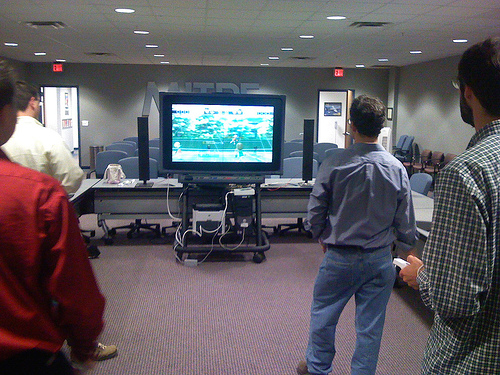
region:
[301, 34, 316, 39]
a small ceiling light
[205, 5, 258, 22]
a white ceiling tile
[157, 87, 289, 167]
a large black t.v.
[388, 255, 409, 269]
part of a white Wii controller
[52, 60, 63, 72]
a red and white emergency exit sign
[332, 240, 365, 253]
a man's black belt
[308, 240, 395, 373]
a man's blue jean pants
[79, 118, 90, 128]
a white light switch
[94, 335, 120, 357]
part of a man's shoe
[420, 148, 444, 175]
a brown chair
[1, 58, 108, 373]
A man in a red shirt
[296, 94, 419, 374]
A man wearing all blue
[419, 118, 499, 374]
A blue and white plaid shirt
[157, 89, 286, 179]
A flat screen tv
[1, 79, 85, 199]
A man in a white shirt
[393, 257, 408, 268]
A video game controller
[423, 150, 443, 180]
A brown chair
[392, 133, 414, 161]
A pair of blue chairs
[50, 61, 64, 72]
An exit sign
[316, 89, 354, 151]
An open door way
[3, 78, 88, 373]
man standing in room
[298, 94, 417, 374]
man standing in room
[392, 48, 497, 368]
man standing in room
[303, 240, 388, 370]
blue jeans of man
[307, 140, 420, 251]
blue shirt of man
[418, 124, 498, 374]
checkered shirt of man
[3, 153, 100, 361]
red shirt of man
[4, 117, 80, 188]
white shirt of man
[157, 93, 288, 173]
large tv in room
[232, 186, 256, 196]
Wii console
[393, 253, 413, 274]
Wii remote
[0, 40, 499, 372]
group of people playing video games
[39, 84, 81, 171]
Open door in the room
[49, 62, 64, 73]
Exit sign posted on top of the ceiling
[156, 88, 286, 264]
Cart with a television set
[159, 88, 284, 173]
Television posted on the cart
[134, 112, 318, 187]
Pair of speakers surrounding the computer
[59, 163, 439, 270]
Desk surrounding the computer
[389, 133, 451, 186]
Row of chairs next to the wall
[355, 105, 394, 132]
Man has dark hair.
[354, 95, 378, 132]
Man has short hair.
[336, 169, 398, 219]
Man wearing blue shirt.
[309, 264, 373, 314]
Man wearing blue jeans.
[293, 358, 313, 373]
Man wearing brown shoes.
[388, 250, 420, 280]
Person holding white controller.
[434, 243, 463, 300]
Person wearing plaid shirt.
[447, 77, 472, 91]
Glasses on person's face.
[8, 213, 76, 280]
Person wearing red shirt.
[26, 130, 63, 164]
Person wearing white shirt.